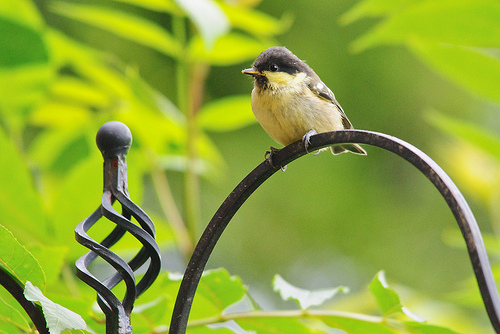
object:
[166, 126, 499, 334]
arch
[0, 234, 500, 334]
ground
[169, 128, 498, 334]
metal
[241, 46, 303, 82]
head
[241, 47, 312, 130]
finch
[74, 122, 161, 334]
pole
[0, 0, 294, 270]
plant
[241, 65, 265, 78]
beak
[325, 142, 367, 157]
tail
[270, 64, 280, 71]
black eye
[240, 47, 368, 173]
bird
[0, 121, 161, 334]
iron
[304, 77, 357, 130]
bird wing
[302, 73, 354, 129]
wing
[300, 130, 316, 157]
bird feet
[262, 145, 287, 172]
foot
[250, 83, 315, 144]
belly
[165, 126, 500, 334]
wire structure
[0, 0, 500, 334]
background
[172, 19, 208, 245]
stock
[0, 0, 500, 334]
leaf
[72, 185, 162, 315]
twist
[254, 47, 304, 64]
bonnet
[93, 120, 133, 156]
top